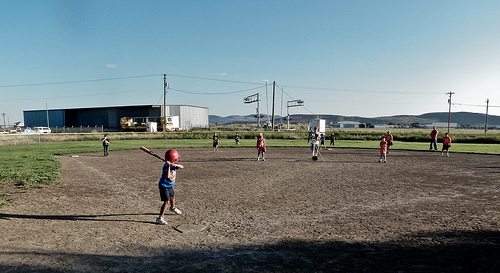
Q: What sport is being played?
A: Baseball.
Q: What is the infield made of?
A: Dirt.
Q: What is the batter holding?
A: A bat.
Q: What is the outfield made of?
A: Grass.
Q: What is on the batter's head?
A: A helmet.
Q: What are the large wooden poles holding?
A: Power lines.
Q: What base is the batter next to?
A: Home plate.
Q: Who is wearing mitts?
A: The fielders.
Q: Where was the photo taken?
A: At a baseball field.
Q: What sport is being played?
A: Baseball.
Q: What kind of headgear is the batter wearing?
A: A helmet.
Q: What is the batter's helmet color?
A: Red.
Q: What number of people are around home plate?
A: One.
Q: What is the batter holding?
A: A baseball bat.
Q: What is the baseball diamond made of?
A: Dirt.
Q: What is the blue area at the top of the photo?
A: The sky.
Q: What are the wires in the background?
A: Power lines.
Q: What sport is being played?
A: Baseball.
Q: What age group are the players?
A: Children.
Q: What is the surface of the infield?
A: Clay.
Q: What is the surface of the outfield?
A: Grass.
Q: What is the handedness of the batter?
A: Right handed.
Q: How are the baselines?
A: Worn.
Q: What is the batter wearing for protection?
A: A helmet.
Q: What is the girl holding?
A: A bat.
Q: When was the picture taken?
A: Daytime.